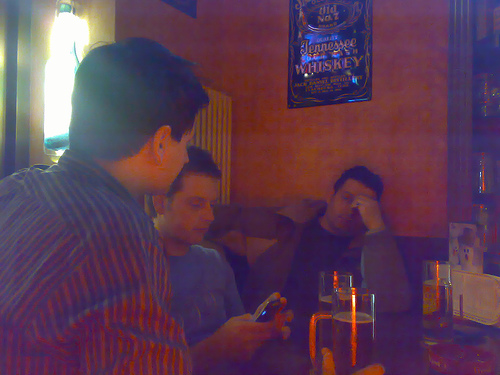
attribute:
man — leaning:
[300, 160, 403, 308]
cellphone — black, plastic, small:
[256, 286, 278, 343]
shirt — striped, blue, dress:
[17, 161, 177, 370]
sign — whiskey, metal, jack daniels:
[287, 7, 379, 109]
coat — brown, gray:
[361, 231, 420, 321]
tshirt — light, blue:
[164, 241, 246, 343]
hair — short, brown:
[74, 56, 216, 158]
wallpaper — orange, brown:
[222, 13, 438, 225]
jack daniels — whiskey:
[285, 38, 370, 81]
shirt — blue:
[170, 239, 249, 342]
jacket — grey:
[345, 232, 411, 296]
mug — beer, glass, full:
[331, 286, 370, 364]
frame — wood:
[2, 7, 33, 168]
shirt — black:
[286, 226, 342, 283]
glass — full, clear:
[317, 270, 376, 364]